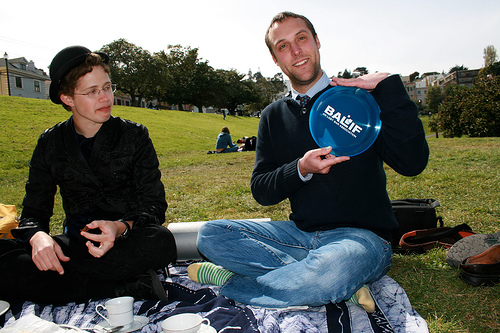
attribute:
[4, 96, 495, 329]
grass — green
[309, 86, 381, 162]
frisbee — blue, white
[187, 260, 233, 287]
sock — striped, green, yellow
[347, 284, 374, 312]
sock — striped, green, yellow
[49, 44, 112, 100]
hat — black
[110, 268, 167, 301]
shoes — black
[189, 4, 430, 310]
person — smiling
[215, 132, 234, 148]
hoodie — blue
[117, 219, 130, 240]
watch — black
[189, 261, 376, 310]
socks — yellow, green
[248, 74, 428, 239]
sweater — dark blue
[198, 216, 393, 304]
jeans — blue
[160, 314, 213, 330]
tea cup — white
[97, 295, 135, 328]
tea cup — white